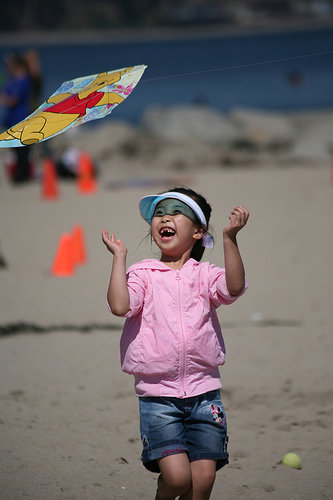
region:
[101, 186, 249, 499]
A very happy little girl.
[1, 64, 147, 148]
A Winnie the Poo kite above the girl's head.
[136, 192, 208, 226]
White sun visor on the girl's head.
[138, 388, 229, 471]
Jean shorts with Mini Mouse near the pocket.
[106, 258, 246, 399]
A solid pink zip up jacket.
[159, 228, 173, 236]
Two missing front baby teeth.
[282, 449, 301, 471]
A green tennis ball on the ground.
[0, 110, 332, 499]
Brown sand on the ground.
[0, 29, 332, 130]
A lake with blue water.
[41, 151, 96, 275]
Orange traffic cones on the ground.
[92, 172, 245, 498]
Girl on the beach.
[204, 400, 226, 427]
Minnie mouse character on shorts.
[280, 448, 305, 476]
Ball in the sand.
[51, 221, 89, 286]
Orange cones on the sand.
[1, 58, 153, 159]
Kite in the air.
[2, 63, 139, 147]
winnie the pooh character on the kite.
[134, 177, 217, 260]
white sun visor on the girl.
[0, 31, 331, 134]
Water in the background.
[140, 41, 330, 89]
White kite string in the air.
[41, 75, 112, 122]
Red shirt on the character.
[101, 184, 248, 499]
Girl on the sand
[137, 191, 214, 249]
Hat on the girl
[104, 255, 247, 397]
Jacket on the girl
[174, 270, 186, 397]
Zipper on the girl's jacket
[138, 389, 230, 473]
Shorts on the girl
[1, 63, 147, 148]
Kite in the sky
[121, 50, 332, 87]
String on the kite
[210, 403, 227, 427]
Mickey mouse on the shorts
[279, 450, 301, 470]
Tennis ball on the sand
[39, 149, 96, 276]
Cones on the sand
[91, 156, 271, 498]
a happy girl on beach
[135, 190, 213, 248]
a white visor on head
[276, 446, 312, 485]
a green ball in the sand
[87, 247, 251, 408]
a pink jacket on girl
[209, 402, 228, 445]
Minnie Mouse on pocket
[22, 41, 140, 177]
a Winnie the Pooh kite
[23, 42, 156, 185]
a kite above the girl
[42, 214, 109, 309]
orange cones in the sand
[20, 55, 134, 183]
a yellow bear on kite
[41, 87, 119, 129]
a red shirt on bear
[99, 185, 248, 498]
little girl looking up at the kit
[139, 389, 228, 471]
blue jean shorts little girl is wearing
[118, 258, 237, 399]
pink jacket the little girl is wearing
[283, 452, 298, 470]
yellow ball in the sand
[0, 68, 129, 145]
picture of a bear on the kit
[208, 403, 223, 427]
logo on little girl's shorts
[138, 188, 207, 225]
white sun visor hat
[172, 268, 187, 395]
zipper down the middle of the pink jacket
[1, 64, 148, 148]
kit flying in the air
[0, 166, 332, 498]
sandy beach young girl is standing on